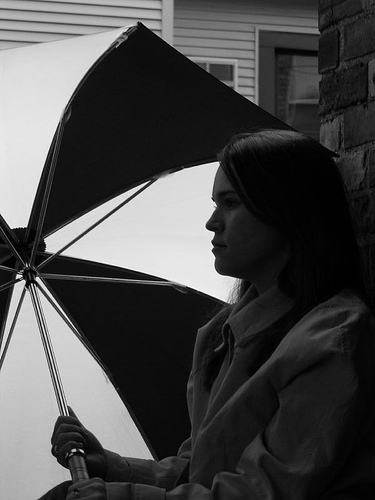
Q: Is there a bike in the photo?
A: No, there are no bikes.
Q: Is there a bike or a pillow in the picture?
A: No, there are no bikes or pillows.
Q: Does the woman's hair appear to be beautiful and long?
A: Yes, the hair is beautiful and long.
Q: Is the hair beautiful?
A: Yes, the hair is beautiful.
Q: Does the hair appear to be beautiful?
A: Yes, the hair is beautiful.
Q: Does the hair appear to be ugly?
A: No, the hair is beautiful.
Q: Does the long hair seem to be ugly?
A: No, the hair is beautiful.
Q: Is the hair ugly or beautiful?
A: The hair is beautiful.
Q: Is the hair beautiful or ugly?
A: The hair is beautiful.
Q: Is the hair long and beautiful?
A: Yes, the hair is long and beautiful.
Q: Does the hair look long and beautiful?
A: Yes, the hair is long and beautiful.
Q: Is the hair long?
A: Yes, the hair is long.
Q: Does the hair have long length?
A: Yes, the hair is long.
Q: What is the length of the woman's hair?
A: The hair is long.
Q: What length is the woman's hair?
A: The hair is long.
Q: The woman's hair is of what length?
A: The hair is long.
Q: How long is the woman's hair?
A: The hair is long.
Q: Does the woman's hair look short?
A: No, the hair is long.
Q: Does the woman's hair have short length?
A: No, the hair is long.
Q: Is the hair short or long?
A: The hair is long.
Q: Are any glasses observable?
A: No, there are no glasses.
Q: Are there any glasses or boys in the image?
A: No, there are no glasses or boys.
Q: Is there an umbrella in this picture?
A: Yes, there is an umbrella.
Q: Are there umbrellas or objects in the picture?
A: Yes, there is an umbrella.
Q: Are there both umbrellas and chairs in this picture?
A: No, there is an umbrella but no chairs.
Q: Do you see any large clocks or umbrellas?
A: Yes, there is a large umbrella.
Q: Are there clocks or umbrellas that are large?
A: Yes, the umbrella is large.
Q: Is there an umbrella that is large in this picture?
A: Yes, there is a large umbrella.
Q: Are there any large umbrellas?
A: Yes, there is a large umbrella.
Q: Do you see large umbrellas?
A: Yes, there is a large umbrella.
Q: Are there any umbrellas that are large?
A: Yes, there is an umbrella that is large.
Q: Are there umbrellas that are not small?
A: Yes, there is a large umbrella.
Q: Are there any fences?
A: No, there are no fences.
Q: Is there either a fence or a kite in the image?
A: No, there are no fences or kites.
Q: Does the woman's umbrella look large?
A: Yes, the umbrella is large.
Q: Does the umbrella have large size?
A: Yes, the umbrella is large.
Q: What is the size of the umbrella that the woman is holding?
A: The umbrella is large.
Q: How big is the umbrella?
A: The umbrella is large.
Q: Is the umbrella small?
A: No, the umbrella is large.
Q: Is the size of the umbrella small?
A: No, the umbrella is large.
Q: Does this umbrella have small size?
A: No, the umbrella is large.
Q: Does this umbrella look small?
A: No, the umbrella is large.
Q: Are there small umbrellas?
A: No, there is an umbrella but it is large.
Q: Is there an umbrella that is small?
A: No, there is an umbrella but it is large.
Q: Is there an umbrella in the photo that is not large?
A: No, there is an umbrella but it is large.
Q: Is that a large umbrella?
A: Yes, that is a large umbrella.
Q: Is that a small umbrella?
A: No, that is a large umbrella.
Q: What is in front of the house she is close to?
A: The umbrella is in front of the house.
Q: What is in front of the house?
A: The umbrella is in front of the house.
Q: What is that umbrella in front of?
A: The umbrella is in front of the house.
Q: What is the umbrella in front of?
A: The umbrella is in front of the house.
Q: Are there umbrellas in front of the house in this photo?
A: Yes, there is an umbrella in front of the house.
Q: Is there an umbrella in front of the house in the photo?
A: Yes, there is an umbrella in front of the house.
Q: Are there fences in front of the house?
A: No, there is an umbrella in front of the house.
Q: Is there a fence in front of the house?
A: No, there is an umbrella in front of the house.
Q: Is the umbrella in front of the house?
A: Yes, the umbrella is in front of the house.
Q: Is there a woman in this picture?
A: Yes, there is a woman.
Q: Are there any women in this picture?
A: Yes, there is a woman.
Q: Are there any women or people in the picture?
A: Yes, there is a woman.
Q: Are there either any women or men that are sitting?
A: Yes, the woman is sitting.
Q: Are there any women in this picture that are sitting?
A: Yes, there is a woman that is sitting.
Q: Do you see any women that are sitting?
A: Yes, there is a woman that is sitting.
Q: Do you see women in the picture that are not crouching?
A: Yes, there is a woman that is sitting .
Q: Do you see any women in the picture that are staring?
A: Yes, there is a woman that is staring.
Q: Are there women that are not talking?
A: Yes, there is a woman that is staring.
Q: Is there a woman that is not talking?
A: Yes, there is a woman that is staring.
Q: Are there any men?
A: No, there are no men.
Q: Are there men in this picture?
A: No, there are no men.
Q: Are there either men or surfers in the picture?
A: No, there are no men or surfers.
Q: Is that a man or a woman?
A: That is a woman.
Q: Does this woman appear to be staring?
A: Yes, the woman is staring.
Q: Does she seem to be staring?
A: Yes, the woman is staring.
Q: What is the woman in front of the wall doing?
A: The woman is staring.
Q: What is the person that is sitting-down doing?
A: The woman is staring.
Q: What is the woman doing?
A: The woman is staring.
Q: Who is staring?
A: The woman is staring.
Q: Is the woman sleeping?
A: No, the woman is staring.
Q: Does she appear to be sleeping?
A: No, the woman is staring.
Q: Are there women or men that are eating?
A: No, there is a woman but she is staring.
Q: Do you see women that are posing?
A: No, there is a woman but she is staring.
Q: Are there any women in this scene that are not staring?
A: No, there is a woman but she is staring.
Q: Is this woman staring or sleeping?
A: The woman is staring.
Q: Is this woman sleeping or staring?
A: The woman is staring.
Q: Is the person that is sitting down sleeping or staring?
A: The woman is staring.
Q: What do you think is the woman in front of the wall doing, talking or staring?
A: The woman is staring.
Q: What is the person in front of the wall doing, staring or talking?
A: The woman is staring.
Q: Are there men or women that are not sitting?
A: No, there is a woman but she is sitting.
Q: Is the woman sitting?
A: Yes, the woman is sitting.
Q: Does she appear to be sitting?
A: Yes, the woman is sitting.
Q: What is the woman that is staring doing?
A: The woman is sitting.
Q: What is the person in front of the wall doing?
A: The woman is sitting.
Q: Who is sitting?
A: The woman is sitting.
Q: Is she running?
A: No, the woman is sitting.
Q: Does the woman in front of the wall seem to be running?
A: No, the woman is sitting.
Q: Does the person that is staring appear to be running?
A: No, the woman is sitting.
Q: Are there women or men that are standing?
A: No, there is a woman but she is sitting.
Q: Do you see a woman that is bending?
A: No, there is a woman but she is sitting.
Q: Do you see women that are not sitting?
A: No, there is a woman but she is sitting.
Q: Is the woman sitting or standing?
A: The woman is sitting.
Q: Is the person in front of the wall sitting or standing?
A: The woman is sitting.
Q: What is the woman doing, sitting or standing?
A: The woman is sitting.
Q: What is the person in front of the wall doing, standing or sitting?
A: The woman is sitting.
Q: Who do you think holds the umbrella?
A: The woman holds the umbrella.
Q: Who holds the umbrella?
A: The woman holds the umbrella.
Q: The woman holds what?
A: The woman holds the umbrella.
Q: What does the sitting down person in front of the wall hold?
A: The woman holds the umbrella.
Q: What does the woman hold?
A: The woman holds the umbrella.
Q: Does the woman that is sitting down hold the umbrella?
A: Yes, the woman holds the umbrella.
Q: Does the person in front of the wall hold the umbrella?
A: Yes, the woman holds the umbrella.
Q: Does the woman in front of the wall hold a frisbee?
A: No, the woman holds the umbrella.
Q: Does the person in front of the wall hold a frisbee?
A: No, the woman holds the umbrella.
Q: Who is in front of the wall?
A: The woman is in front of the wall.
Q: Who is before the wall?
A: The woman is in front of the wall.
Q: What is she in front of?
A: The woman is in front of the wall.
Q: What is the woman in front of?
A: The woman is in front of the wall.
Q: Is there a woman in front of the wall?
A: Yes, there is a woman in front of the wall.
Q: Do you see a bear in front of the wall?
A: No, there is a woman in front of the wall.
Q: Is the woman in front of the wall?
A: Yes, the woman is in front of the wall.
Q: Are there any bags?
A: No, there are no bags.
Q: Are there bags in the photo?
A: No, there are no bags.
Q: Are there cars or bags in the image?
A: No, there are no bags or cars.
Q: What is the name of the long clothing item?
A: The clothing item is a raincoat.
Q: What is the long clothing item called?
A: The clothing item is a raincoat.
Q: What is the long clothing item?
A: The clothing item is a raincoat.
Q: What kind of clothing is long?
A: The clothing is a raincoat.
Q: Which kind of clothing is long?
A: The clothing is a raincoat.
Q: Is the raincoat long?
A: Yes, the raincoat is long.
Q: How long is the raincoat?
A: The raincoat is long.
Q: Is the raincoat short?
A: No, the raincoat is long.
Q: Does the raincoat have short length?
A: No, the raincoat is long.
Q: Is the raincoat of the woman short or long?
A: The raincoat is long.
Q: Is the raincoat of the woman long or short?
A: The raincoat is long.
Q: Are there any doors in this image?
A: Yes, there is a door.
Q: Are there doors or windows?
A: Yes, there is a door.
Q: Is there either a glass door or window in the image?
A: Yes, there is a glass door.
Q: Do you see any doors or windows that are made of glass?
A: Yes, the door is made of glass.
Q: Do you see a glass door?
A: Yes, there is a door that is made of glass.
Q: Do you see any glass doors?
A: Yes, there is a door that is made of glass.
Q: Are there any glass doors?
A: Yes, there is a door that is made of glass.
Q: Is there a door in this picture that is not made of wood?
A: Yes, there is a door that is made of glass.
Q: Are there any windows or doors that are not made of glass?
A: No, there is a door but it is made of glass.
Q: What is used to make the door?
A: The door is made of glass.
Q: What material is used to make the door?
A: The door is made of glass.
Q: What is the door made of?
A: The door is made of glass.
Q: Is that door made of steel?
A: No, the door is made of glass.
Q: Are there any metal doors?
A: No, there is a door but it is made of glass.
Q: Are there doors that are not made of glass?
A: No, there is a door but it is made of glass.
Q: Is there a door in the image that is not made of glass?
A: No, there is a door but it is made of glass.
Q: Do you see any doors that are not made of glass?
A: No, there is a door but it is made of glass.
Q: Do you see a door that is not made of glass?
A: No, there is a door but it is made of glass.